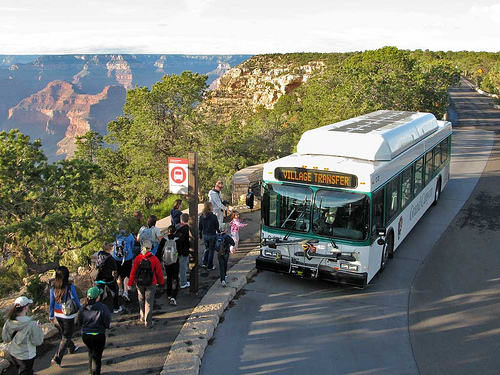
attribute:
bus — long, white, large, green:
[260, 108, 450, 287]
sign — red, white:
[168, 157, 200, 197]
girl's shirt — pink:
[231, 217, 239, 231]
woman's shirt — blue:
[116, 235, 135, 259]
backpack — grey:
[167, 241, 175, 262]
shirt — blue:
[45, 284, 81, 317]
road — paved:
[225, 71, 499, 374]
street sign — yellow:
[478, 68, 484, 73]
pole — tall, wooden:
[187, 154, 203, 295]